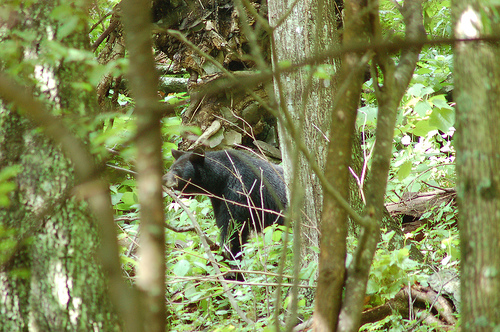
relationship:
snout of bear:
[163, 169, 178, 189] [161, 144, 296, 281]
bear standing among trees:
[160, 142, 309, 272] [0, 5, 485, 330]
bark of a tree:
[468, 273, 494, 311] [324, 40, 490, 328]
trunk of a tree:
[448, 0, 499, 331] [186, 26, 376, 326]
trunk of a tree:
[267, 0, 420, 308] [223, 88, 403, 284]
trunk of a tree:
[267, 0, 420, 308] [259, 66, 362, 303]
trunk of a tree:
[267, 0, 420, 308] [267, 75, 379, 296]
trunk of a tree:
[267, 0, 420, 308] [240, 65, 372, 285]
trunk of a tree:
[311, 58, 359, 310] [25, 70, 485, 306]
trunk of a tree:
[448, 0, 499, 331] [25, 70, 485, 306]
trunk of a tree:
[112, 3, 172, 323] [25, 70, 485, 306]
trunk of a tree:
[0, 0, 125, 331] [25, 70, 485, 306]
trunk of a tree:
[263, 10, 345, 290] [25, 70, 485, 306]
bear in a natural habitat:
[161, 144, 288, 281] [0, 0, 499, 331]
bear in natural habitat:
[161, 144, 288, 281] [3, 5, 490, 331]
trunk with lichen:
[267, 0, 420, 308] [267, 0, 341, 265]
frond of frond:
[330, 56, 481, 260] [428, 107, 452, 132]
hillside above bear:
[167, 2, 269, 147] [159, 142, 289, 248]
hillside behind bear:
[167, 2, 269, 147] [159, 142, 289, 248]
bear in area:
[161, 144, 288, 281] [36, 59, 164, 281]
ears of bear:
[172, 145, 206, 165] [159, 142, 289, 248]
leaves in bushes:
[113, 190, 130, 207] [177, 210, 282, 325]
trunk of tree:
[0, 0, 125, 331] [2, 0, 165, 330]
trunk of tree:
[448, 0, 499, 331] [450, 0, 496, 330]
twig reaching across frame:
[161, 58, 291, 108] [2, 0, 497, 327]